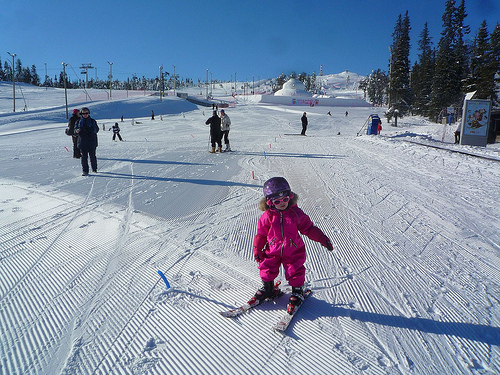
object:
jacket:
[251, 208, 326, 260]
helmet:
[263, 175, 290, 195]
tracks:
[0, 153, 136, 333]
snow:
[0, 61, 500, 375]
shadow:
[284, 287, 500, 348]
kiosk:
[458, 92, 494, 146]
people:
[206, 111, 222, 155]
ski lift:
[74, 66, 96, 77]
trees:
[465, 22, 500, 145]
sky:
[0, 0, 497, 83]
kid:
[247, 176, 337, 305]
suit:
[254, 209, 331, 288]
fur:
[259, 200, 269, 210]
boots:
[289, 283, 306, 309]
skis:
[271, 286, 316, 332]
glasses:
[80, 112, 91, 118]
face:
[78, 110, 92, 120]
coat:
[77, 119, 102, 148]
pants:
[79, 148, 98, 173]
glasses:
[270, 197, 290, 204]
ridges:
[251, 144, 278, 173]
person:
[75, 106, 100, 178]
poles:
[311, 134, 349, 201]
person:
[302, 111, 310, 136]